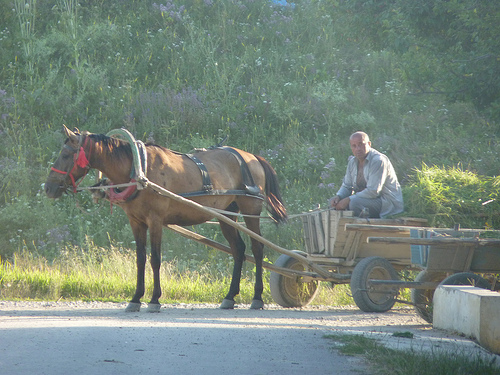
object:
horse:
[43, 122, 291, 312]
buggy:
[269, 216, 432, 313]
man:
[328, 131, 403, 219]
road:
[76, 306, 106, 328]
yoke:
[104, 127, 144, 182]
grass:
[435, 181, 456, 199]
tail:
[253, 153, 289, 229]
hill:
[192, 26, 264, 50]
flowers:
[263, 88, 266, 99]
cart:
[343, 223, 500, 325]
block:
[431, 284, 499, 354]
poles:
[366, 236, 483, 247]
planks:
[419, 255, 424, 262]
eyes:
[62, 154, 70, 159]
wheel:
[350, 256, 400, 313]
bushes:
[12, 46, 25, 72]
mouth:
[51, 183, 62, 199]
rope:
[252, 215, 259, 218]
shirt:
[335, 147, 404, 219]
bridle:
[76, 146, 89, 169]